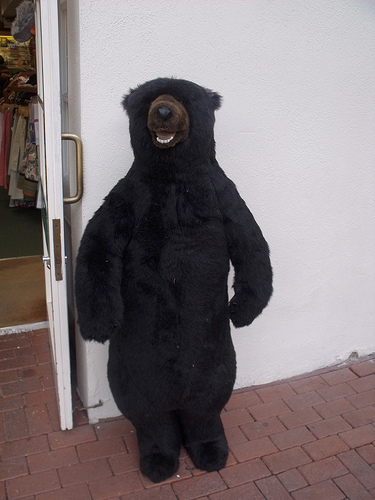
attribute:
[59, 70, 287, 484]
bear — stuffed, smiling, standing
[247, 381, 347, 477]
brick — red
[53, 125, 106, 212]
handle — silver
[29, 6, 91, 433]
door — white, silver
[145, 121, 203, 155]
teeth — white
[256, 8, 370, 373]
wall — white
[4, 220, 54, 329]
floor — wood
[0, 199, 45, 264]
carpet — green